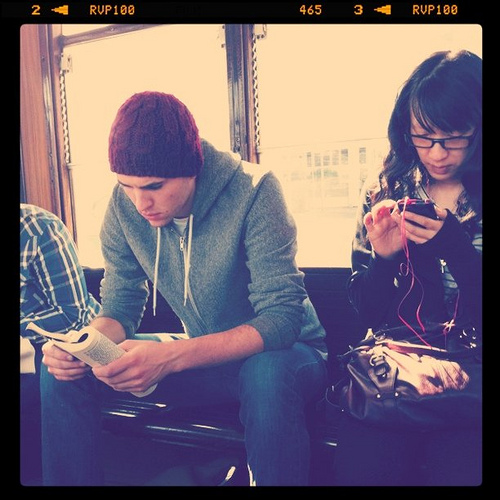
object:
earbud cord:
[400, 201, 457, 349]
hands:
[364, 201, 407, 261]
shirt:
[95, 137, 330, 349]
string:
[151, 223, 161, 315]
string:
[182, 209, 192, 305]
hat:
[107, 89, 205, 178]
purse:
[328, 325, 478, 430]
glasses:
[401, 127, 476, 150]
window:
[59, 25, 227, 262]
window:
[251, 24, 480, 272]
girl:
[345, 47, 487, 404]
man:
[38, 89, 330, 484]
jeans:
[37, 325, 328, 485]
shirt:
[347, 142, 493, 365]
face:
[407, 102, 477, 181]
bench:
[81, 267, 485, 496]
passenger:
[5, 204, 94, 485]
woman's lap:
[378, 353, 479, 490]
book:
[27, 321, 159, 398]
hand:
[91, 337, 163, 391]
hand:
[40, 339, 90, 382]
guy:
[39, 92, 329, 500]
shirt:
[15, 204, 101, 348]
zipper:
[179, 238, 183, 250]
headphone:
[403, 194, 413, 208]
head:
[107, 91, 206, 229]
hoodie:
[94, 138, 328, 351]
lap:
[359, 327, 471, 398]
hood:
[184, 137, 241, 223]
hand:
[394, 198, 453, 252]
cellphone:
[397, 198, 438, 221]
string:
[439, 288, 462, 330]